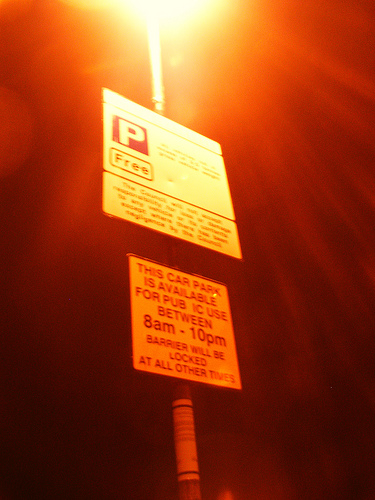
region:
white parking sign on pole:
[99, 96, 239, 248]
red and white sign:
[111, 117, 150, 157]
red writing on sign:
[104, 192, 197, 223]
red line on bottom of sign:
[120, 170, 175, 200]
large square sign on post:
[130, 269, 232, 383]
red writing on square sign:
[120, 271, 227, 373]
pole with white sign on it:
[165, 386, 206, 498]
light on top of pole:
[100, 0, 188, 85]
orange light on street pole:
[137, 0, 190, 57]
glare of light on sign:
[200, 92, 357, 354]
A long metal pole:
[129, 0, 208, 499]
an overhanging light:
[104, 0, 210, 36]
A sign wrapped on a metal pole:
[167, 397, 200, 480]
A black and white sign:
[123, 247, 243, 387]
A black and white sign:
[99, 83, 243, 260]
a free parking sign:
[99, 84, 243, 260]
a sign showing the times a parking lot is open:
[123, 250, 245, 388]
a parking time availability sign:
[123, 249, 243, 385]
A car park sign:
[99, 83, 241, 255]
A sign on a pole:
[125, 251, 246, 391]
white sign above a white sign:
[101, 86, 242, 261]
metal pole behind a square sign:
[171, 377, 202, 498]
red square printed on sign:
[110, 114, 150, 155]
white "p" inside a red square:
[117, 119, 146, 146]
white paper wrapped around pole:
[171, 398, 201, 482]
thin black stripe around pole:
[171, 401, 194, 410]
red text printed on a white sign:
[134, 261, 236, 383]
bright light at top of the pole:
[76, 0, 228, 22]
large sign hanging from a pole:
[101, 86, 245, 261]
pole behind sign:
[164, 239, 202, 498]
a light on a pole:
[83, 0, 234, 106]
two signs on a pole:
[87, 28, 259, 496]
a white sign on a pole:
[85, 82, 253, 267]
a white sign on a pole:
[120, 250, 250, 401]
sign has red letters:
[84, 78, 252, 262]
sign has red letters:
[120, 246, 245, 403]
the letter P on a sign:
[94, 97, 157, 162]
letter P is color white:
[107, 105, 153, 161]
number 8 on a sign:
[137, 308, 157, 335]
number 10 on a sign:
[189, 324, 207, 346]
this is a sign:
[100, 80, 241, 259]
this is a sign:
[115, 249, 250, 395]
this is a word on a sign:
[133, 255, 174, 281]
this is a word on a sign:
[163, 267, 191, 286]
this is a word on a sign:
[193, 271, 229, 296]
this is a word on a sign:
[139, 271, 158, 288]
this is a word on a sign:
[132, 279, 164, 304]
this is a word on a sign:
[156, 289, 189, 314]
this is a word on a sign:
[192, 298, 239, 323]